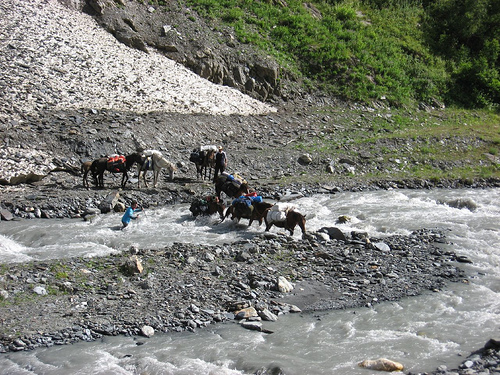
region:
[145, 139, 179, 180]
white horse next to a river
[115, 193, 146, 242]
man standing in a river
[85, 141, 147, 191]
brown horse next to a river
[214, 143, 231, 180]
man next to a river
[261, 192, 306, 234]
horse crossing a river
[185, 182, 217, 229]
horse crossing a river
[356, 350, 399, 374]
rock in a river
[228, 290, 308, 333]
rocks on the riverbed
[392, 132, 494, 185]
grass next to a river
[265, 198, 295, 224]
pack on a horse's back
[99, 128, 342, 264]
Group of horses gathered together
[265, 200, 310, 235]
Horse carrying a load of stuff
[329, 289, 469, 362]
The river is fast moving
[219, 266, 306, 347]
Large rock beside the river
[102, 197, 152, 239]
Person in the water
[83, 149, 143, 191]
Horse has a baby with it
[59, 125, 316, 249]
All the horses are carrying large loads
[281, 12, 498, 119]
Group of scrub bushes on ground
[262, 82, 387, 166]
Small pebbles in the grass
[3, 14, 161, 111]
hill covered in stones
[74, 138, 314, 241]
horses by a fast moving river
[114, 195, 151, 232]
a person is in a river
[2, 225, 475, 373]
an island of rocks in the middle of a river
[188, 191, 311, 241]
horses crossing a river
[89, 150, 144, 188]
a dark brown horse with an orange blanket on its back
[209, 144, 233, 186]
a man stands on the riverbank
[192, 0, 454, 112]
shrubs and bushes growing on a hillside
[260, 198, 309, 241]
a horse carries goods across a river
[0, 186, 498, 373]
river water is moving rapidly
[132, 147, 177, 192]
a white horse has its head lowered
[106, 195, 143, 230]
a man guiding animals across a river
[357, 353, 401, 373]
a white stone in the water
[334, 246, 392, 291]
large stone scattered on the ground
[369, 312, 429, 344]
currents in the river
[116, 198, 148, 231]
a man wearing a blue shirt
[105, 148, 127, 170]
a red and black pack on the horse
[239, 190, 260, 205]
a blue and red pack on the horse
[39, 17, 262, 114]
a steep rocky hill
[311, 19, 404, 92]
small green shrubs on the hill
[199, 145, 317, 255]
brown horses crossing the river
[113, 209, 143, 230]
the top is blue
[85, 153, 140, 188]
the horse has a red bag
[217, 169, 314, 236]
the donkeys are crossing the river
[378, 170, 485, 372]
the river is flowing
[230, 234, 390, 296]
pebbles are on the river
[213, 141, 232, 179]
the man has a hat on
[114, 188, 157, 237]
the guy is in the river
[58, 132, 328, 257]
the horse are six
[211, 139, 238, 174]
the hat is grown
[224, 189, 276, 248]
the horse has luggage